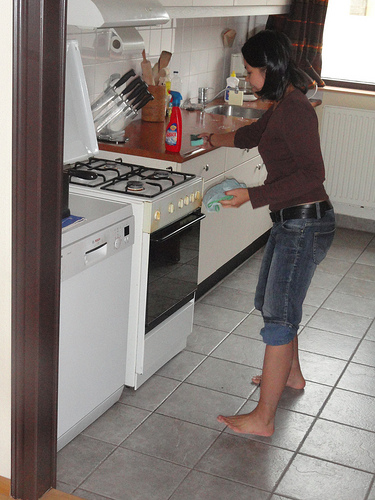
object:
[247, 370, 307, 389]
foot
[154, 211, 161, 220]
dial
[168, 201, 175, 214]
dial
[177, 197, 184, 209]
dial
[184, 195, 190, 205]
dial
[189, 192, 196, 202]
dial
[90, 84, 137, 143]
knife rack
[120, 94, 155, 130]
knife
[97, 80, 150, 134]
knife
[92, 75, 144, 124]
knife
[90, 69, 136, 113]
knife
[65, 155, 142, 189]
burner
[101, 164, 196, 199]
burner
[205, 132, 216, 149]
bracelet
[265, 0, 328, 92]
curtains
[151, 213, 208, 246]
knobs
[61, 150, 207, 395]
stove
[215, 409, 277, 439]
no shoes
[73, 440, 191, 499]
tile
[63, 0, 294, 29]
top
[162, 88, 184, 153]
bottle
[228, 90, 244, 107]
soap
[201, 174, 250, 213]
sponge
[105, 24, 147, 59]
rack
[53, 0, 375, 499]
kitchen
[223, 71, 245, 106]
cleaner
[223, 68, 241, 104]
bottle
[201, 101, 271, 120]
sink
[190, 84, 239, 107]
faucet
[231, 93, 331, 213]
shirt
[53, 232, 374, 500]
flooring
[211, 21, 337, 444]
woman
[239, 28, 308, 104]
hair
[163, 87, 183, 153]
cleaner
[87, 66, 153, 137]
utensils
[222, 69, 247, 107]
maker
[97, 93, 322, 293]
counter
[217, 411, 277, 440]
feet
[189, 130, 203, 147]
cleaning tools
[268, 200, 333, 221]
belt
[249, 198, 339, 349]
pants